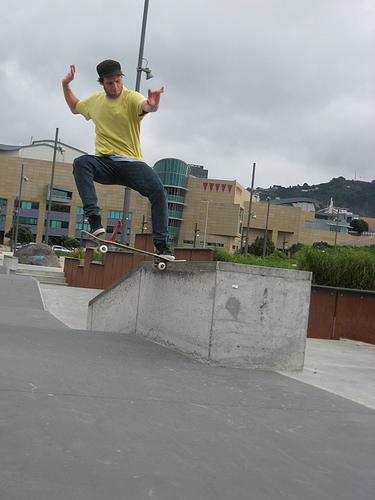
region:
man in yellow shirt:
[61, 53, 181, 256]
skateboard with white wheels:
[79, 227, 185, 271]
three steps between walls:
[6, 252, 77, 290]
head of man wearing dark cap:
[91, 54, 126, 101]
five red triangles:
[198, 179, 237, 195]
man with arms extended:
[55, 55, 178, 274]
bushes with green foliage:
[216, 241, 374, 295]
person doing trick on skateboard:
[56, 55, 191, 360]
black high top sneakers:
[85, 208, 179, 264]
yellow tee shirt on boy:
[72, 85, 146, 162]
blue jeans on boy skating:
[62, 154, 172, 238]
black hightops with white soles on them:
[87, 213, 172, 259]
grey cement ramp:
[81, 258, 318, 367]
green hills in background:
[248, 173, 372, 215]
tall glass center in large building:
[151, 156, 193, 264]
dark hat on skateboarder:
[96, 56, 124, 77]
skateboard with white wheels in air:
[76, 230, 186, 270]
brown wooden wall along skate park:
[61, 233, 211, 301]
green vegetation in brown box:
[207, 245, 372, 293]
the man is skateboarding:
[48, 20, 198, 293]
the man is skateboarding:
[48, 49, 209, 331]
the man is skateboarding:
[36, 49, 191, 331]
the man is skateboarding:
[49, 47, 194, 319]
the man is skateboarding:
[53, 52, 211, 324]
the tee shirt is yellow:
[73, 93, 156, 174]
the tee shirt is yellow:
[81, 84, 160, 174]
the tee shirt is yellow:
[72, 83, 150, 164]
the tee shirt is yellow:
[72, 82, 149, 172]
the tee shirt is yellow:
[68, 85, 143, 168]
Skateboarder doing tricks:
[61, 56, 182, 266]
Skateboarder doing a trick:
[60, 57, 184, 267]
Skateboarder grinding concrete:
[60, 58, 310, 376]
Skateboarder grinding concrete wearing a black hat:
[61, 55, 310, 370]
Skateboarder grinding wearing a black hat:
[61, 57, 186, 272]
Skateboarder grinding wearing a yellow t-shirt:
[59, 59, 187, 272]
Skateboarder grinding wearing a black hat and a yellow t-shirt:
[59, 58, 188, 270]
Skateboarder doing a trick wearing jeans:
[61, 58, 188, 271]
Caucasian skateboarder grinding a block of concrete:
[61, 58, 186, 271]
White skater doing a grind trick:
[56, 56, 187, 274]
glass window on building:
[20, 202, 25, 208]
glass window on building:
[26, 201, 32, 211]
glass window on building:
[31, 202, 37, 208]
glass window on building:
[106, 209, 109, 217]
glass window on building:
[109, 209, 114, 218]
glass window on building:
[56, 220, 60, 229]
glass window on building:
[60, 219, 68, 227]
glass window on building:
[50, 221, 55, 227]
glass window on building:
[29, 217, 36, 223]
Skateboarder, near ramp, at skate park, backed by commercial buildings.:
[1, 2, 372, 499]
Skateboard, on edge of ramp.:
[87, 230, 186, 275]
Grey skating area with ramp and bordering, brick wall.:
[4, 246, 368, 493]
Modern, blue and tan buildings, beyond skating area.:
[0, 155, 374, 247]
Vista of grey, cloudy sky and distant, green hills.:
[293, 113, 370, 208]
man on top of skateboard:
[49, 60, 180, 260]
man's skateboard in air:
[78, 224, 186, 271]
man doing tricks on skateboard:
[54, 55, 182, 260]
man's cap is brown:
[90, 55, 125, 80]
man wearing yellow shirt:
[71, 85, 150, 162]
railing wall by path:
[82, 254, 311, 375]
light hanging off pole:
[137, 56, 155, 82]